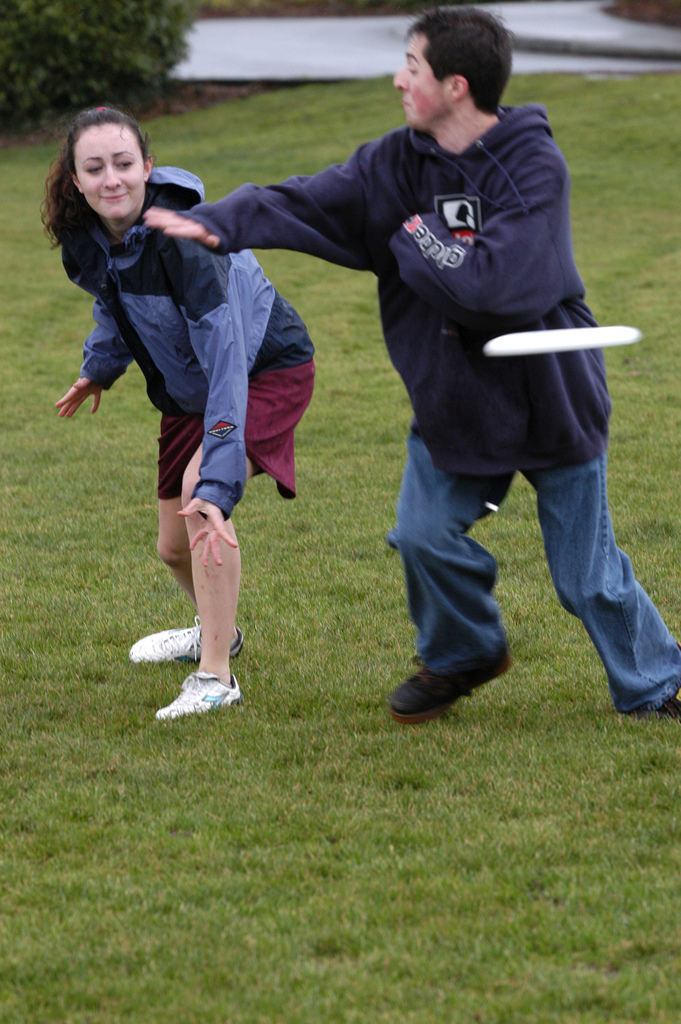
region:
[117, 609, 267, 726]
Woman wearing shoes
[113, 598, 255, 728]
Woman is wearing shoes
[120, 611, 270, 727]
Woman wearing white shoes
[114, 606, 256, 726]
Woman is wearing white shoes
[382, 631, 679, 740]
Man wearing shoes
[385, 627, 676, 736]
Man wearing black and brown shoes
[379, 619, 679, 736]
Man is wearing black and brown shoes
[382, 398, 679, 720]
Man wearing blue jeans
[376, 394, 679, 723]
Man is wearing blue jeans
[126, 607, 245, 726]
a pair of white sneakers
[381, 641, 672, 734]
the dark colored shoes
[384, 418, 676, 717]
a pair of pants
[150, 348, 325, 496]
an above the knee skirt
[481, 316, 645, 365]
a white frisbee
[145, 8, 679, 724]
a guy in the park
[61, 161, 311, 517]
a blue jacket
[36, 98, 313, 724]
a lady playing frisbee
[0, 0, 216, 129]
a bush on the left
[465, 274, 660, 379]
this is a white flying disc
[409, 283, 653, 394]
this is a white frisbee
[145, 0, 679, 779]
he is wearing a blue hoodie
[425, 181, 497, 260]
this is the Globe skateboard logo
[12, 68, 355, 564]
she is wearing a blue rain jacket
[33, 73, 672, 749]
she just threw the frisbee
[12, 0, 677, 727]
he is trying to block her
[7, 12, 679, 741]
they are on a grass field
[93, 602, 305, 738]
her shoes are white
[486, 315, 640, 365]
the white frisbee being thrown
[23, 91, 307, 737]
the girl throwing the frisbee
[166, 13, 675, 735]
the boy playing the frisbee game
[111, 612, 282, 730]
the white sneakers on the girl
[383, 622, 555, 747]
the black sneaker of the guy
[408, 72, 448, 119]
The boys red cheeks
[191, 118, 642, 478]
the blue hoodie the boy is wearing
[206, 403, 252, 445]
the label on the girls jacket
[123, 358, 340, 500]
the girls re shirts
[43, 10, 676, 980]
Two people playing with disc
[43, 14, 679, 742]
Two people playing in the park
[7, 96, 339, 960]
Girl wearing shoes no socks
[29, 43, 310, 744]
Girl with no socks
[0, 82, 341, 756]
Woman with blue jacket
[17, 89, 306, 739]
Woman with blue jacket and red shorts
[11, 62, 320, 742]
Young woman with red shorts and jacket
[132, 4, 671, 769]
male wearing dark blue sweatshirt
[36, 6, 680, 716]
man and woman in the park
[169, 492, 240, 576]
Hand of a woman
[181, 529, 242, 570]
Fingers on a hand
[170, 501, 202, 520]
Thumb on a hand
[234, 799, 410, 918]
Large patch of grass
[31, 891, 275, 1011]
Large patch of grass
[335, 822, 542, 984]
Large patch of grass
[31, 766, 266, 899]
Large patch of grass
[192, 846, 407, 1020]
Large patch of grass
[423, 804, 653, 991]
Large patch of grass